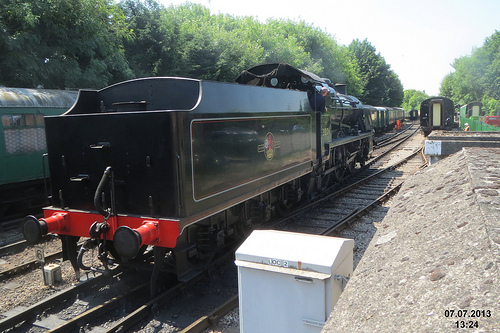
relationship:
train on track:
[23, 60, 374, 287] [0, 117, 427, 332]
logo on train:
[262, 131, 280, 166] [23, 60, 374, 287]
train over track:
[23, 60, 374, 287] [0, 117, 427, 332]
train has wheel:
[23, 60, 374, 287] [299, 171, 331, 200]